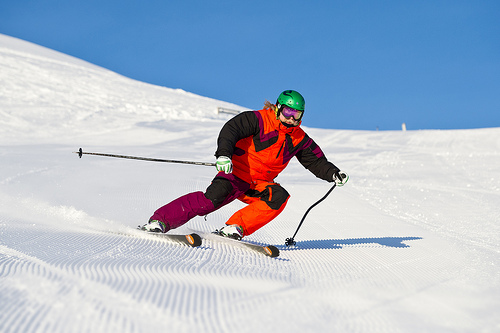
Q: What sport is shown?
A: Skiing.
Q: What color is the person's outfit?
A: Orange, black, purple.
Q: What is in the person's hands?
A: Ski poles.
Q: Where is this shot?
A: Slopes.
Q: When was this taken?
A: Daytime.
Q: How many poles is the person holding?
A: 2.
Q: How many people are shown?
A: 1.